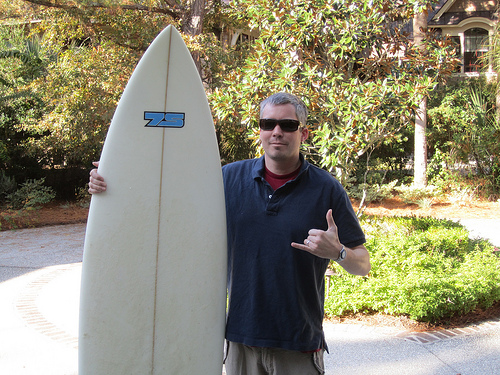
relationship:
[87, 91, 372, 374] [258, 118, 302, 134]
man wearing sunglasses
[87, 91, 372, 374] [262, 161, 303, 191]
man wearing undershirt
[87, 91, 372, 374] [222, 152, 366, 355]
man wearing shirt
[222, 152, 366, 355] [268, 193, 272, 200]
shirt has button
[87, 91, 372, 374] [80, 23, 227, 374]
man holding surfboard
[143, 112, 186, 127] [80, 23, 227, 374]
sticker stuck on surfboard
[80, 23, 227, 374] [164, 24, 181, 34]
surfboard has tip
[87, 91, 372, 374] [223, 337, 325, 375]
man wearing pants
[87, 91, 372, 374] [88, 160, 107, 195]
man has hand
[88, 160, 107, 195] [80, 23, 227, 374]
hand holding surfboard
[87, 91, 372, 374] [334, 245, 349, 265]
man wearing watch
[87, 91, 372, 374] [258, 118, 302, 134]
man wears sunglasses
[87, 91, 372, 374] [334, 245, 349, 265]
man wears watch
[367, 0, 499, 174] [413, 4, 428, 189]
building behind tree trunk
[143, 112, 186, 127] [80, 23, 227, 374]
sticker attached to surfboard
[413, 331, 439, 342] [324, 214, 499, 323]
brick around bush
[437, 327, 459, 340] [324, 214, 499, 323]
brick around bush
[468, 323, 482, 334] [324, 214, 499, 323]
brick around bush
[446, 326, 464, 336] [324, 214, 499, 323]
brick around bush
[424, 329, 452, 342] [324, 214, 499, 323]
brick around bush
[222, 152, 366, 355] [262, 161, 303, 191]
shirt over undershirt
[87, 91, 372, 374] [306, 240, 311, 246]
man wearing wedding band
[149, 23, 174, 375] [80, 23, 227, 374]
line through middle of surfboard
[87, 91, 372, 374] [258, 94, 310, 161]
man has head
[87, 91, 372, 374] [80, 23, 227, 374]
man loves surfboard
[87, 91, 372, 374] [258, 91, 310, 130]
man has hair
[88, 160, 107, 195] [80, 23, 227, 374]
hand around surfboard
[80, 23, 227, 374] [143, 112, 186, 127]
surfboard has sticker